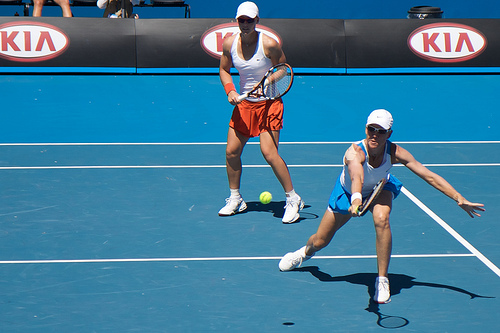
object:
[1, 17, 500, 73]
barrier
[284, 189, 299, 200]
sock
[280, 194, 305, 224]
foot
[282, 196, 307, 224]
shoe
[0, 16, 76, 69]
wall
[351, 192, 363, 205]
wrist band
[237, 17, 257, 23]
sunglasses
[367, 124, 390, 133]
sunglasses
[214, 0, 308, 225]
man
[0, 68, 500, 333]
tennis court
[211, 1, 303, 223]
lady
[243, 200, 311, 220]
shadow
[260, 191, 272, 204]
ball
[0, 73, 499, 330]
court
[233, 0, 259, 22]
hat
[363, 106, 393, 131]
hat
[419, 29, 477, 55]
kia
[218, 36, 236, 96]
arm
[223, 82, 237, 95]
band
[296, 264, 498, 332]
shadow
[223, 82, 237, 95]
wrist band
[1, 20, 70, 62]
kia logo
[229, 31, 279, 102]
shirt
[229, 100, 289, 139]
shorts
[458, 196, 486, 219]
hand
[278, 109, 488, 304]
man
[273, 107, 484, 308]
lady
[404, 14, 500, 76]
wall